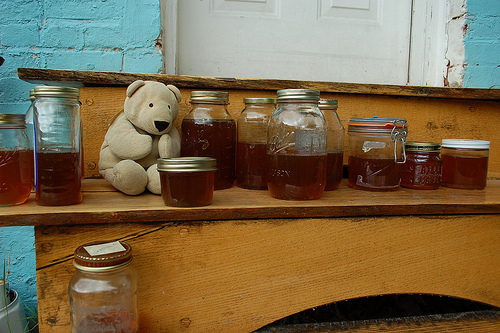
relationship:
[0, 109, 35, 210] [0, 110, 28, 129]
jar has lid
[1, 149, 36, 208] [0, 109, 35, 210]
something in jar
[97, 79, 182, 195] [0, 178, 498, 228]
bear on shelf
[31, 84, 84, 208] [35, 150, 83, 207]
jar has honey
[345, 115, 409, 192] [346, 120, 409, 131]
jar has rubber seal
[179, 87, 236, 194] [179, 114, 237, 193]
jar with honey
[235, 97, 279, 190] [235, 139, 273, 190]
jar of honey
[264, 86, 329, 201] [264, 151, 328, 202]
jar of honey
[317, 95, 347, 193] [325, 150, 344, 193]
jar of honey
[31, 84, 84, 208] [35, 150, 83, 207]
jar of honey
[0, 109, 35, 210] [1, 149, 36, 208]
jar of honey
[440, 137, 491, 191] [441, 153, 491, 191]
jar of honey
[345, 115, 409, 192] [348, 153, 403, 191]
jar of honey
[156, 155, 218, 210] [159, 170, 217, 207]
jar of honey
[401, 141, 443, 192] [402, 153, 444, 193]
jar of honey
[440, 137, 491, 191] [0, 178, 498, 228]
jar of shelf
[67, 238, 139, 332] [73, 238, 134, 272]
jar with lid